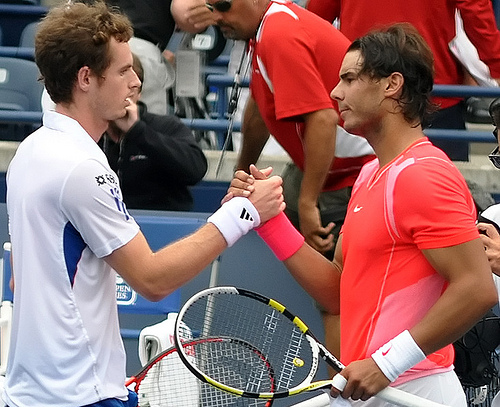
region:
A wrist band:
[351, 304, 418, 404]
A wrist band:
[380, 266, 422, 377]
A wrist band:
[373, 321, 440, 376]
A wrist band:
[357, 283, 474, 399]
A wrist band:
[316, 299, 393, 401]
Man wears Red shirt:
[346, 156, 428, 348]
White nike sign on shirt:
[347, 196, 369, 221]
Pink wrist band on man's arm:
[258, 206, 308, 264]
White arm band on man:
[196, 189, 272, 247]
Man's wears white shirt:
[18, 139, 60, 284]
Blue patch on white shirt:
[55, 218, 93, 292]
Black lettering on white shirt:
[91, 164, 118, 186]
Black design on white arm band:
[237, 203, 256, 229]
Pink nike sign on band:
[376, 339, 396, 356]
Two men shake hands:
[208, 141, 298, 242]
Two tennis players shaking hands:
[0, 2, 496, 402]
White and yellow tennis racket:
[165, 280, 460, 401]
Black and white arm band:
[190, 185, 265, 245]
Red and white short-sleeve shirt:
[225, 1, 391, 196]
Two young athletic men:
[1, 0, 498, 404]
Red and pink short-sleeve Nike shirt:
[316, 140, 496, 385]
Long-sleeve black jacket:
[94, 97, 210, 211]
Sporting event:
[0, 0, 498, 404]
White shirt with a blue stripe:
[5, 106, 147, 404]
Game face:
[311, 26, 449, 149]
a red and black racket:
[119, 335, 280, 405]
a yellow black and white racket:
[168, 282, 458, 405]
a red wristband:
[257, 210, 305, 264]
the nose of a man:
[125, 65, 144, 87]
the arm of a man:
[257, 28, 342, 204]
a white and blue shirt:
[6, 111, 139, 405]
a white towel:
[137, 313, 207, 405]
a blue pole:
[429, 83, 499, 95]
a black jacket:
[87, 100, 208, 212]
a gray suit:
[1, 54, 44, 115]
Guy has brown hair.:
[376, 29, 429, 121]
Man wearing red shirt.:
[333, 192, 384, 304]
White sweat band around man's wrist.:
[348, 336, 433, 404]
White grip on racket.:
[382, 376, 417, 405]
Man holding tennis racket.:
[278, 335, 370, 392]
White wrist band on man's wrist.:
[188, 178, 263, 277]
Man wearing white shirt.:
[30, 185, 92, 315]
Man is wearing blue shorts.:
[103, 374, 132, 401]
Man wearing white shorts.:
[367, 375, 430, 400]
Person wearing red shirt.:
[266, 75, 310, 120]